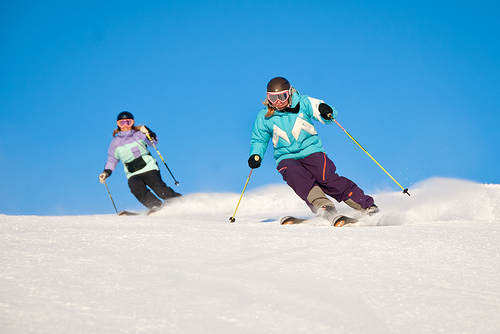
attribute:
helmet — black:
[253, 63, 301, 104]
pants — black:
[122, 157, 198, 228]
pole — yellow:
[133, 114, 192, 190]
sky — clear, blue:
[111, 34, 202, 73]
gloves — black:
[233, 131, 278, 179]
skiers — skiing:
[66, 59, 429, 260]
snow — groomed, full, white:
[32, 221, 213, 305]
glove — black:
[244, 152, 273, 169]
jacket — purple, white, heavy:
[88, 116, 173, 186]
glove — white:
[93, 166, 111, 192]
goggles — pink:
[263, 85, 301, 106]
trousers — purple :
[276, 151, 389, 231]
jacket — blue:
[240, 85, 333, 174]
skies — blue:
[111, 29, 224, 90]